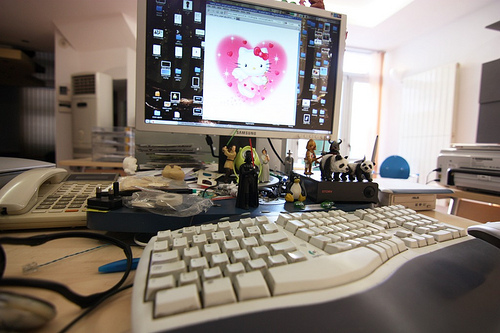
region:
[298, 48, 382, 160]
natural light through window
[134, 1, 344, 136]
image on computer screen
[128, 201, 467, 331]
white buttons on keyboard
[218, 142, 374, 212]
figurines on blue surface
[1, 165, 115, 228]
buttons on top of phone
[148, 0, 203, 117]
icons on computer screen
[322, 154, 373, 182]
two panda bear figurines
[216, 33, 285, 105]
hello kitty in heart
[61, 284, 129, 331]
black wire on table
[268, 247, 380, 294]
long white plain button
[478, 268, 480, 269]
part of a table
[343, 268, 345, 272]
edge of a laptop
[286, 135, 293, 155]
part of a screen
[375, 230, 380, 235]
part of a table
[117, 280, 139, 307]
part of a rope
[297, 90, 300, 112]
part of a screen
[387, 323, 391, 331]
edge of a table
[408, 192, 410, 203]
part of a window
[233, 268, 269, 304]
white button on keyboard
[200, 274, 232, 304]
white button on keyboard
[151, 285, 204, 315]
white button on keyboard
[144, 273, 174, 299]
white button on keyboard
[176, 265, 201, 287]
white button on keyboard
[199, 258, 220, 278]
white button on keyboard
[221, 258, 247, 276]
white button on keyboard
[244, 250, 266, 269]
white button on keyboard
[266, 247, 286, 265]
white button on keyboard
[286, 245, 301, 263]
white button on keyboard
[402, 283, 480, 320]
The desk is black.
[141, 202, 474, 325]
The keyboard is white.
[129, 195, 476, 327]
The keyboard is on the desk.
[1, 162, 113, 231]
The phone is white.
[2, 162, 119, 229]
The phone is on the desk.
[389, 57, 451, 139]
The door is white.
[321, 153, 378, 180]
The panda's are white and black.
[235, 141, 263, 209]
Darth Vader is on the desk.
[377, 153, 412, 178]
The ball in the background is blue.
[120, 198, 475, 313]
The keyboard in front of the monitor.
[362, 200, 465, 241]
The number pad of the keyboard.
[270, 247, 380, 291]
The spacebar on the keyboard.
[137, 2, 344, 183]
The computer monitor.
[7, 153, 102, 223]
The phone on the left.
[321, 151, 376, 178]
The panda bear figurines.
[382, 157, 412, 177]
The blue ball in the distance.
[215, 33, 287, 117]
Hello Kitty on the screen.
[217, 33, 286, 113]
The pink heart around Hello Kitty.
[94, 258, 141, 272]
The blue lid of the pen.